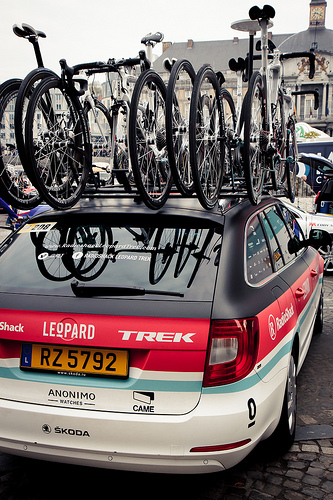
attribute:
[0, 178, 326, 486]
car — black, red, white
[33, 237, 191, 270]
letters — white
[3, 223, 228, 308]
window — back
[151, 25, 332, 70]
roof — gray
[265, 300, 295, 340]
letters — white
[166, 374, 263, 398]
stripe car — blue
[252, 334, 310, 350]
stripe car — blue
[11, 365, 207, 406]
stripe car — blue